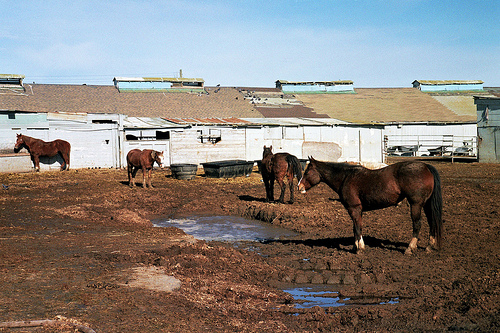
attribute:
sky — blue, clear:
[3, 1, 500, 87]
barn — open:
[0, 73, 500, 172]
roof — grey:
[0, 74, 480, 124]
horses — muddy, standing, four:
[16, 130, 444, 257]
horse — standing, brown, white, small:
[299, 156, 444, 254]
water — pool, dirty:
[150, 209, 305, 246]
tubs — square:
[200, 157, 255, 177]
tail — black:
[429, 164, 444, 251]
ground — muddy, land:
[1, 163, 499, 330]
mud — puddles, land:
[269, 264, 344, 285]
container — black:
[202, 158, 254, 176]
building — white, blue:
[0, 72, 479, 171]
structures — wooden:
[0, 71, 499, 170]